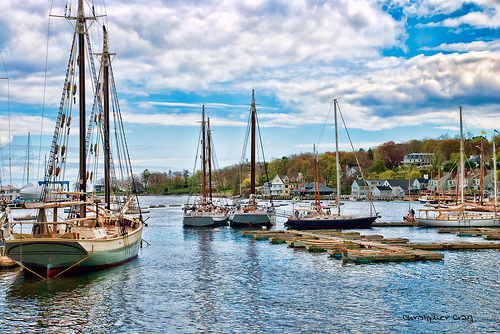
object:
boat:
[284, 207, 382, 228]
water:
[0, 194, 500, 331]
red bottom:
[19, 255, 146, 282]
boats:
[302, 95, 499, 245]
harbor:
[4, 192, 474, 331]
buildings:
[341, 175, 415, 207]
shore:
[342, 196, 422, 223]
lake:
[3, 32, 498, 332]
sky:
[408, 27, 457, 56]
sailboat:
[0, 40, 154, 316]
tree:
[184, 168, 191, 183]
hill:
[97, 137, 495, 198]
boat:
[11, 202, 152, 275]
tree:
[249, 153, 429, 201]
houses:
[286, 173, 408, 210]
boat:
[180, 99, 227, 231]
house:
[399, 148, 439, 170]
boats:
[157, 76, 395, 241]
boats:
[184, 194, 299, 240]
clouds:
[1, 3, 485, 145]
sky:
[0, 5, 462, 166]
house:
[262, 175, 289, 195]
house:
[349, 172, 381, 194]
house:
[412, 178, 428, 189]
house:
[427, 170, 447, 191]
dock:
[279, 226, 435, 269]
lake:
[161, 225, 201, 288]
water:
[13, 200, 185, 309]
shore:
[181, 174, 495, 197]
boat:
[401, 204, 493, 227]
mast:
[193, 94, 216, 210]